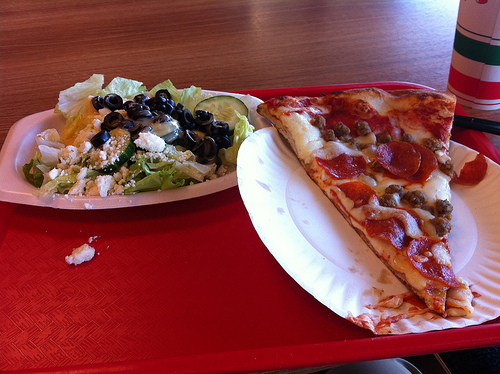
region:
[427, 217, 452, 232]
sausage topping on a slice of pizza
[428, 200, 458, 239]
two pieces of sausage on a slice of pizza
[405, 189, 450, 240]
three pieces of sausage on a slice of pizza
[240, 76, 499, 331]
slice of sausage and pepperoni pizza on white plate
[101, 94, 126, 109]
slice of black olive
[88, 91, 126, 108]
two slices of olive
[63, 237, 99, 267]
piece of chicken on a red tray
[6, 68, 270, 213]
chicken salad topped with black olives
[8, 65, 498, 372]
slice of pizza and salad on a red tray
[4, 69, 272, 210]
plate of salad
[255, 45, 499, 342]
The pizza is on the paper plate.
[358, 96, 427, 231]
The pizza have sausage and pepporoni.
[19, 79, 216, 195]
A salad is next to the pizza.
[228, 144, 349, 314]
The paper plate is white.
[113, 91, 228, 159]
Black olives on top of the salad.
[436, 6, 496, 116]
A cup is sitting on the table.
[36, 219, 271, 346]
The table is red.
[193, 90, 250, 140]
A green cucumber in the salad.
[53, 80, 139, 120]
The salad has lettuce in it.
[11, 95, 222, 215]
The salad is on a white tray.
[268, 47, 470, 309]
slice of pizza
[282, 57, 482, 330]
peperoni and beef pizza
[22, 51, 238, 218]
side salad to compliment pizza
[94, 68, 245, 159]
black olives in salad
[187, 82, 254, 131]
cucumber slices in salad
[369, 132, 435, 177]
pepperoni on pizza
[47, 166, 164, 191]
feta cheese on salad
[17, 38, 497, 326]
pizza, salad, and drink combo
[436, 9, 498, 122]
beverage cup with italian colors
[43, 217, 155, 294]
spilt feta cheese on lunch tray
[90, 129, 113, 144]
Black olive on salad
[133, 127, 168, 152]
White cheese crumb on salad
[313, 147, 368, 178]
Pepperoni slice on pizza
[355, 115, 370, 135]
Beef sausage on pizza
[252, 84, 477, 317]
Pizza on white round plastic plate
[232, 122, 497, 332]
Plastic white plate on red tray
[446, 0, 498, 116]
Cup by red tray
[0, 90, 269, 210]
Salad tray on red tray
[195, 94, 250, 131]
Cucumber in salad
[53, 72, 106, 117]
Lettuce on salad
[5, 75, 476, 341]
pizza and salad on a red tray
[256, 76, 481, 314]
slice of pizza shaped like a triangle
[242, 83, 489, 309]
pizza is on a white paper plate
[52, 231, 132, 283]
crumb of cheese on red tray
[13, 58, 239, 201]
salad is in pink bowl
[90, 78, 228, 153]
sliced black olives are on the salad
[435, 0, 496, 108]
white cup has two stripes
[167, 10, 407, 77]
red tray is on wooden table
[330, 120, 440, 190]
pepperoni is on the pizza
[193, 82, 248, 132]
slice of cucumber